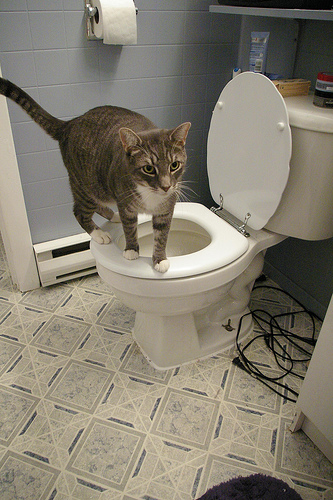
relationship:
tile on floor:
[54, 399, 166, 498] [0, 245, 332, 499]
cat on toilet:
[1, 80, 196, 273] [91, 73, 331, 372]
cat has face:
[1, 80, 196, 273] [144, 156, 182, 194]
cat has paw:
[1, 80, 196, 273] [154, 254, 168, 272]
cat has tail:
[1, 80, 196, 273] [0, 84, 63, 142]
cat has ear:
[1, 80, 196, 273] [118, 127, 141, 152]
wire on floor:
[233, 282, 316, 404] [0, 245, 332, 499]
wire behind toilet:
[233, 282, 316, 404] [91, 73, 331, 372]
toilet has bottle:
[91, 73, 331, 372] [315, 70, 332, 104]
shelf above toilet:
[209, 0, 327, 23] [91, 73, 331, 372]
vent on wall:
[34, 235, 98, 284] [2, 1, 239, 248]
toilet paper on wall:
[88, 2, 140, 47] [2, 1, 239, 248]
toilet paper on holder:
[88, 2, 140, 47] [85, 4, 138, 18]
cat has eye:
[1, 80, 196, 273] [144, 167, 158, 173]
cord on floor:
[233, 282, 316, 404] [0, 245, 332, 499]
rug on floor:
[199, 471, 305, 498] [0, 245, 332, 499]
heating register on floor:
[34, 235, 98, 284] [0, 245, 332, 499]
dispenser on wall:
[88, 2, 140, 47] [2, 1, 239, 248]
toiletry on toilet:
[310, 75, 331, 109] [91, 73, 331, 372]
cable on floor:
[233, 282, 316, 404] [0, 245, 332, 499]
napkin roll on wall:
[88, 2, 140, 47] [2, 1, 239, 248]